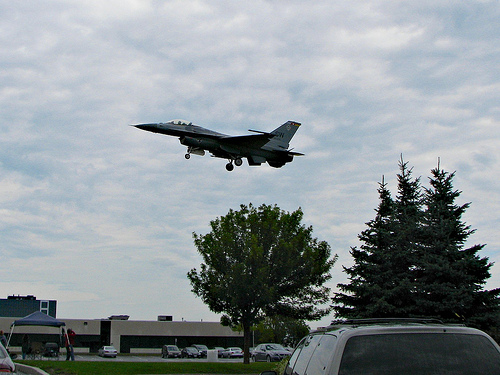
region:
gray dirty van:
[265, 311, 499, 373]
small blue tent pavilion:
[0, 310, 81, 368]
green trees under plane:
[185, 160, 495, 315]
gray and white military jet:
[110, 100, 367, 177]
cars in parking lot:
[95, 340, 292, 361]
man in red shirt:
[55, 315, 95, 365]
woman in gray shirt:
[6, 330, 36, 362]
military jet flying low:
[100, 75, 335, 165]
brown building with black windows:
[103, 319, 255, 361]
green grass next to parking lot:
[71, 355, 281, 372]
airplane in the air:
[116, 106, 321, 181]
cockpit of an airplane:
[161, 114, 203, 131]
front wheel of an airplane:
[179, 140, 196, 164]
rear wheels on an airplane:
[218, 153, 247, 171]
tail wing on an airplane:
[260, 115, 307, 150]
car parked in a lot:
[93, 343, 121, 359]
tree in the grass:
[178, 196, 337, 369]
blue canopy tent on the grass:
[4, 308, 79, 366]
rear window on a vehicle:
[333, 327, 498, 371]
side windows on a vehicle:
[278, 330, 340, 374]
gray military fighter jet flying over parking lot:
[124, 106, 307, 175]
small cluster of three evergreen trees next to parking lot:
[329, 148, 498, 355]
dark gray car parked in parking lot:
[272, 314, 497, 374]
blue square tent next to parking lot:
[2, 309, 77, 367]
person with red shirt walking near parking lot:
[60, 324, 79, 363]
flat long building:
[0, 310, 255, 355]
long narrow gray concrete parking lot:
[0, 346, 321, 362]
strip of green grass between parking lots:
[0, 356, 499, 374]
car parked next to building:
[96, 341, 121, 360]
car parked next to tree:
[249, 337, 296, 365]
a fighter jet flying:
[128, 95, 327, 187]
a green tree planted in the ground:
[193, 185, 315, 367]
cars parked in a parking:
[160, 342, 255, 360]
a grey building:
[5, 295, 62, 318]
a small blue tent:
[7, 307, 89, 361]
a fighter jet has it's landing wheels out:
[130, 101, 305, 190]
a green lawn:
[14, 357, 265, 373]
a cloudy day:
[2, 45, 469, 107]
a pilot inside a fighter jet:
[162, 111, 198, 131]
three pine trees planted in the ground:
[353, 165, 493, 327]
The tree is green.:
[231, 248, 290, 293]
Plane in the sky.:
[129, 115, 298, 162]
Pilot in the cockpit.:
[156, 114, 198, 148]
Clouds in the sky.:
[71, 40, 152, 72]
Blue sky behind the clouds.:
[418, 36, 499, 80]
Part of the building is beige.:
[136, 317, 187, 345]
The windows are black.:
[136, 334, 171, 349]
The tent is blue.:
[19, 305, 60, 332]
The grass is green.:
[113, 358, 189, 374]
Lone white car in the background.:
[101, 342, 131, 358]